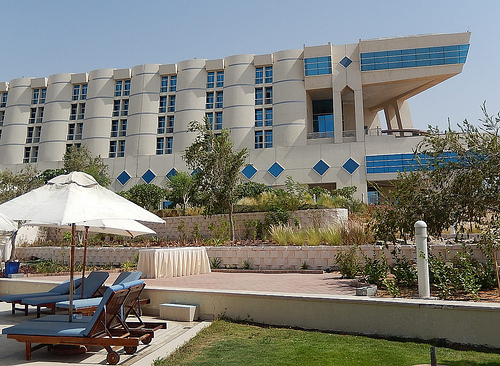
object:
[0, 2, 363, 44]
sky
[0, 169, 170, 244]
umbrella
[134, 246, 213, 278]
tablecloth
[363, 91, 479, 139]
deck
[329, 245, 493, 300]
shrubs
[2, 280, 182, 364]
pool deck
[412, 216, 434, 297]
barricade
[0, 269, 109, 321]
chair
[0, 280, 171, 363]
chair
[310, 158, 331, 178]
design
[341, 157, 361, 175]
design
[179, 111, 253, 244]
tree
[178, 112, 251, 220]
leaves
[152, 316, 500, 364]
ground surface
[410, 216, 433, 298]
pole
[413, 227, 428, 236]
light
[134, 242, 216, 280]
table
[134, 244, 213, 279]
curtain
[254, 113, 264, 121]
windows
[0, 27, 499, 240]
building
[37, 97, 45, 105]
window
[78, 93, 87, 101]
window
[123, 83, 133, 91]
window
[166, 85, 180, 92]
window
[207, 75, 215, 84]
window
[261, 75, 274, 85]
window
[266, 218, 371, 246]
grass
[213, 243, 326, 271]
wall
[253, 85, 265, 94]
window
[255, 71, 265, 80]
window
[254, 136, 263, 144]
window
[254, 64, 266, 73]
window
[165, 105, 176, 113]
window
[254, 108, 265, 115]
window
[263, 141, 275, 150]
window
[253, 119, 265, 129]
window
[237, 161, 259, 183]
diamonds